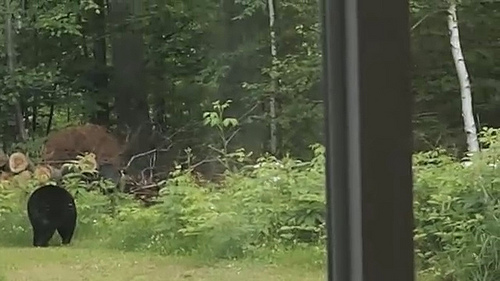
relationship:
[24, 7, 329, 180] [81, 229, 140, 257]
trees behind field